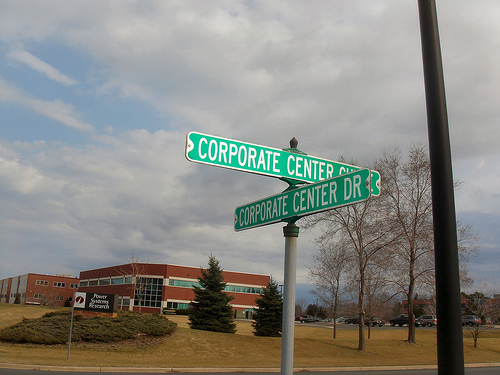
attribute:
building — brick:
[76, 261, 273, 320]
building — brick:
[0, 273, 76, 308]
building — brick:
[400, 296, 436, 316]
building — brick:
[464, 295, 499, 317]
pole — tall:
[175, 103, 367, 244]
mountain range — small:
[306, 280, 437, 330]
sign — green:
[183, 132, 388, 194]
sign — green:
[228, 172, 393, 229]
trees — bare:
[315, 175, 433, 365]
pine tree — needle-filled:
[191, 253, 238, 336]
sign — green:
[185, 130, 382, 197]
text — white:
[180, 127, 382, 231]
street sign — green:
[232, 167, 381, 232]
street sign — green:
[181, 131, 383, 196]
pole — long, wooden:
[391, 32, 485, 182]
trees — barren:
[316, 151, 413, 356]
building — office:
[72, 260, 275, 335]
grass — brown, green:
[181, 331, 238, 365]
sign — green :
[227, 168, 384, 233]